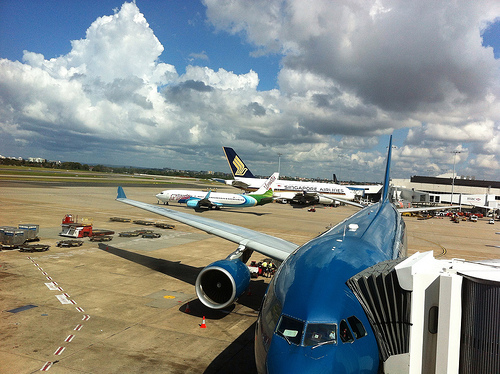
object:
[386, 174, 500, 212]
building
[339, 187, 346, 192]
lettering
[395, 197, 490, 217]
walkway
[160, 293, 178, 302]
spot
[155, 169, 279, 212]
planes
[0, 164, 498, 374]
airport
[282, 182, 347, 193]
writing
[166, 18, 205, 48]
blue sky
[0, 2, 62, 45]
part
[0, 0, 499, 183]
sky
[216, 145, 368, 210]
plane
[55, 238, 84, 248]
flat carts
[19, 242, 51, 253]
flat carts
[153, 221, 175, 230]
flat carts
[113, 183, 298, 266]
wing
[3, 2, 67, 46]
blue sky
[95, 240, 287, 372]
shadow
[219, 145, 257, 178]
plane part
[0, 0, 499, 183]
cloud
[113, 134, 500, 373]
plane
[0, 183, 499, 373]
tarmac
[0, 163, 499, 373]
ground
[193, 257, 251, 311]
jet engine